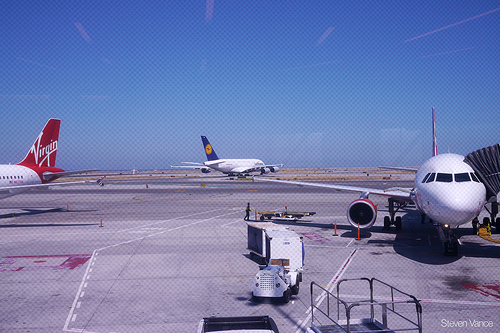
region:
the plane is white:
[1, 113, 27, 229]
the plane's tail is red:
[21, 108, 87, 183]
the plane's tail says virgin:
[16, 102, 63, 187]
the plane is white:
[216, 145, 275, 183]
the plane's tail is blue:
[186, 127, 219, 164]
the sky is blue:
[1, 1, 495, 172]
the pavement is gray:
[1, 168, 471, 323]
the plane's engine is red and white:
[335, 187, 426, 254]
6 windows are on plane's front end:
[412, 153, 495, 200]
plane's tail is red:
[406, 76, 459, 155]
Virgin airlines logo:
[2, 103, 92, 203]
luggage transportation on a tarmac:
[230, 207, 320, 328]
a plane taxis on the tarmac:
[163, 129, 309, 198]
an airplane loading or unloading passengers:
[238, 98, 496, 270]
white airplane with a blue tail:
[168, 121, 300, 187]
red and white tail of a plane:
[1, 103, 86, 208]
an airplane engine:
[339, 173, 395, 245]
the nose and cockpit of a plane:
[411, 146, 488, 236]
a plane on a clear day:
[141, 64, 308, 196]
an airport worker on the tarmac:
[240, 196, 325, 240]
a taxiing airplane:
[165, 133, 289, 183]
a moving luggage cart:
[236, 211, 308, 305]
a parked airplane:
[248, 102, 498, 255]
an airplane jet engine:
[344, 189, 381, 238]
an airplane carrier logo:
[13, 110, 64, 190]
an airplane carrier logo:
[195, 128, 218, 159]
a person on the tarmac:
[237, 198, 252, 218]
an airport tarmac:
[1, 170, 496, 330]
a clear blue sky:
[0, 0, 495, 165]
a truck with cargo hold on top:
[297, 268, 427, 332]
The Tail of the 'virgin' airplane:
[0, 116, 103, 202]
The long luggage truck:
[237, 217, 307, 308]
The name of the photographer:
[438, 314, 495, 331]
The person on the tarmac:
[240, 199, 255, 225]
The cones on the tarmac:
[60, 198, 362, 242]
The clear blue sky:
[0, 0, 498, 169]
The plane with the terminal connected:
[244, 102, 490, 256]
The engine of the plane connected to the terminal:
[345, 194, 381, 234]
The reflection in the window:
[1, 0, 497, 196]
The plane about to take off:
[167, 130, 284, 177]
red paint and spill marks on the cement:
[423, 263, 499, 305]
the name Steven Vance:
[431, 308, 498, 330]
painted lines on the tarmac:
[32, 231, 163, 329]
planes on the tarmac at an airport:
[1, 69, 496, 331]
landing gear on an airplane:
[368, 182, 418, 244]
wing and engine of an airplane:
[225, 170, 438, 240]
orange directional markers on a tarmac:
[60, 192, 135, 245]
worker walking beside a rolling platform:
[226, 186, 326, 232]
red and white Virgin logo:
[8, 98, 103, 216]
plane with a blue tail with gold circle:
[168, 116, 285, 192]